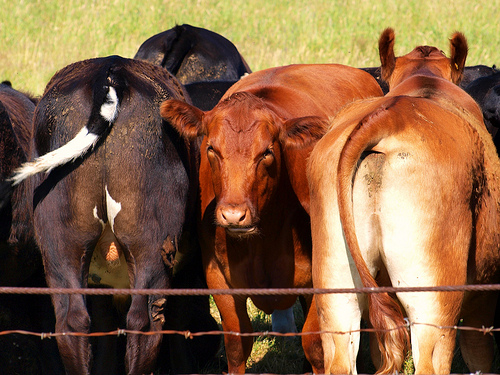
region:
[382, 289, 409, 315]
part of a tail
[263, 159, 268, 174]
eye of a cow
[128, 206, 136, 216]
back of a cow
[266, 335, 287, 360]
part of a fence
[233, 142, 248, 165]
face of a cow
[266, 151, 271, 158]
eye of a cow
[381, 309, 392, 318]
part of a tail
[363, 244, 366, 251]
side of a tail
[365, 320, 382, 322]
part of a tail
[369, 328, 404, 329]
tail of a cow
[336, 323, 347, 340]
back of a leg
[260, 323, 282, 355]
part of the ground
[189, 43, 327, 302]
the cow is brown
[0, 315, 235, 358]
the barb wire is rusty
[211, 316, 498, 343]
the barb wire is rusty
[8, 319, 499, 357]
the barb wire is rusty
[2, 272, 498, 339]
the barb wire is rusty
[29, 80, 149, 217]
a black and white tail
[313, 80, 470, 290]
a brown butt of cow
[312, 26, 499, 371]
Rear end of brown cow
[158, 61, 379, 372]
Brown cow facing forward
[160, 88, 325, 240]
Brown cow with sun shinning down on it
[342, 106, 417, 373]
Swinging tail on brown cow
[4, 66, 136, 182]
White and black cow tail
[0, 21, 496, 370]
Large herd of black and brown cows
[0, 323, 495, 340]
Rusted barbed wire fence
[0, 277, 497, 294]
Rusted metal wire across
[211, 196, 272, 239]
Brown cow chewing grass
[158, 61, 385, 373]
Light brown cow fur coat